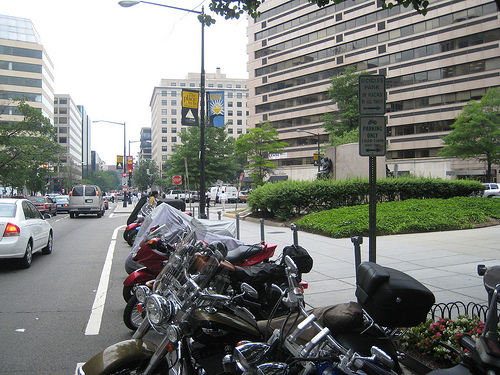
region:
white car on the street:
[0, 186, 67, 275]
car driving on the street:
[54, 178, 107, 230]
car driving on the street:
[19, 193, 60, 216]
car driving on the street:
[45, 193, 72, 222]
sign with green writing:
[351, 61, 402, 127]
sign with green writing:
[352, 111, 394, 161]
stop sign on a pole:
[167, 172, 182, 196]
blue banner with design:
[204, 84, 227, 135]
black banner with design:
[176, 86, 200, 128]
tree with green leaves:
[235, 113, 285, 215]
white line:
[74, 280, 114, 328]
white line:
[61, 245, 121, 352]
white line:
[86, 277, 123, 347]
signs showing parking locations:
[352, 70, 389, 160]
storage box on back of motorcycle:
[353, 259, 434, 330]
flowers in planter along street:
[397, 312, 491, 368]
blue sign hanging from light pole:
[204, 90, 229, 131]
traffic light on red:
[52, 176, 62, 186]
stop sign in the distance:
[170, 175, 185, 185]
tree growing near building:
[445, 100, 498, 175]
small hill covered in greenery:
[289, 196, 496, 233]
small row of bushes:
[247, 175, 484, 210]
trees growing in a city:
[168, 123, 292, 199]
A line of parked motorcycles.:
[115, 185, 485, 371]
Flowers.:
[410, 290, 490, 365]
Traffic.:
[0, 177, 115, 307]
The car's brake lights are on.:
[0, 215, 31, 265]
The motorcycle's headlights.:
[120, 270, 210, 365]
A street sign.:
[340, 60, 400, 290]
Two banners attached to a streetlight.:
[165, 75, 230, 140]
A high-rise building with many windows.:
[145, 75, 250, 195]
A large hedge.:
[250, 165, 490, 210]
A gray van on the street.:
[61, 176, 106, 216]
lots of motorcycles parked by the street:
[68, 202, 363, 372]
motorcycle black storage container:
[352, 256, 442, 339]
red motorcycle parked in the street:
[119, 214, 298, 299]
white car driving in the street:
[2, 191, 65, 266]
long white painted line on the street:
[74, 219, 125, 362]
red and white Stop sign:
[165, 169, 196, 213]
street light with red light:
[122, 149, 144, 184]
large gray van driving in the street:
[65, 177, 115, 220]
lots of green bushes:
[247, 141, 496, 240]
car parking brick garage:
[289, 139, 499, 201]